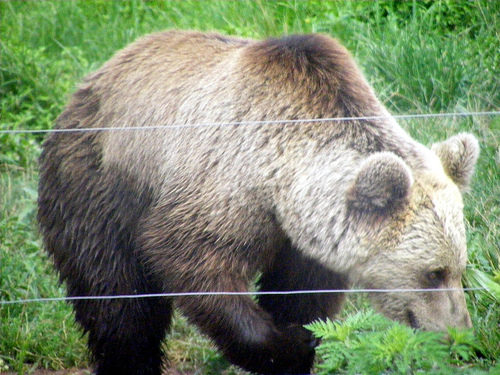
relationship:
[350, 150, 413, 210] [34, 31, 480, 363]
ear on bear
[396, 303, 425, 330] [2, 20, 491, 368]
mouth on bear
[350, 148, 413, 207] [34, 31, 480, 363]
ear of bear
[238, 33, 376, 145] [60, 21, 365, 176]
streak on back